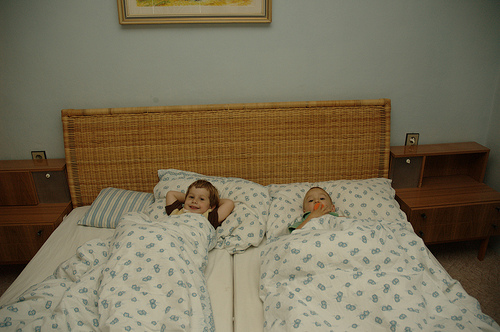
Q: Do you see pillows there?
A: Yes, there is a pillow.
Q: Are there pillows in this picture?
A: Yes, there is a pillow.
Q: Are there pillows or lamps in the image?
A: Yes, there is a pillow.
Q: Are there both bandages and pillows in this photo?
A: No, there is a pillow but no bandages.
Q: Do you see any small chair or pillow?
A: Yes, there is a small pillow.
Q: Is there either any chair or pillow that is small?
A: Yes, the pillow is small.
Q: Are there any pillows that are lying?
A: Yes, there is a pillow that is lying.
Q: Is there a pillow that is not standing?
A: Yes, there is a pillow that is lying.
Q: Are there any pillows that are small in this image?
A: Yes, there is a small pillow.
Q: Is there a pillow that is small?
A: Yes, there is a pillow that is small.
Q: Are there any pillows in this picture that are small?
A: Yes, there is a pillow that is small.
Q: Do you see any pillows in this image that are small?
A: Yes, there is a pillow that is small.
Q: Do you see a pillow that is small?
A: Yes, there is a pillow that is small.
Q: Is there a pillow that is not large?
A: Yes, there is a small pillow.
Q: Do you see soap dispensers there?
A: No, there are no soap dispensers.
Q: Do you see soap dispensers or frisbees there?
A: No, there are no soap dispensers or frisbees.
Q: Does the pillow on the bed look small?
A: Yes, the pillow is small.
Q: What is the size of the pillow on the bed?
A: The pillow is small.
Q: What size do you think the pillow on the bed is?
A: The pillow is small.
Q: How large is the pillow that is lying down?
A: The pillow is small.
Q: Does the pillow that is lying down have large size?
A: No, the pillow is small.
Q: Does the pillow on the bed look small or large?
A: The pillow is small.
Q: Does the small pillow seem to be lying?
A: Yes, the pillow is lying.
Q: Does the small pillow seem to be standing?
A: No, the pillow is lying.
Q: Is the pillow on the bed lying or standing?
A: The pillow is lying.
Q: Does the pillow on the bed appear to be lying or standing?
A: The pillow is lying.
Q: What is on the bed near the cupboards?
A: The pillow is on the bed.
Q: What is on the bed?
A: The pillow is on the bed.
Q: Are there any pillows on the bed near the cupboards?
A: Yes, there is a pillow on the bed.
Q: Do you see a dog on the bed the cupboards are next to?
A: No, there is a pillow on the bed.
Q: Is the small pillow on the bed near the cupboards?
A: Yes, the pillow is on the bed.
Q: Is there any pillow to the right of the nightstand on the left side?
A: Yes, there is a pillow to the right of the nightstand.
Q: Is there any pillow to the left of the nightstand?
A: No, the pillow is to the right of the nightstand.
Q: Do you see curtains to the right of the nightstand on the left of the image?
A: No, there is a pillow to the right of the nightstand.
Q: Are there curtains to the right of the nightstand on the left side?
A: No, there is a pillow to the right of the nightstand.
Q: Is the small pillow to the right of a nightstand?
A: Yes, the pillow is to the right of a nightstand.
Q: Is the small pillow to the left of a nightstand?
A: No, the pillow is to the right of a nightstand.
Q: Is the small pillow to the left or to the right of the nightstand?
A: The pillow is to the right of the nightstand.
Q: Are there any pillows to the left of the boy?
A: Yes, there is a pillow to the left of the boy.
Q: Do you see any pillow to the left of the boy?
A: Yes, there is a pillow to the left of the boy.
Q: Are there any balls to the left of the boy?
A: No, there is a pillow to the left of the boy.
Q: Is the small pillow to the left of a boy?
A: Yes, the pillow is to the left of a boy.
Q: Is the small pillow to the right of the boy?
A: No, the pillow is to the left of the boy.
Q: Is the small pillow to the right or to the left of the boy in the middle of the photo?
A: The pillow is to the left of the boy.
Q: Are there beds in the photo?
A: Yes, there is a bed.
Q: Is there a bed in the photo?
A: Yes, there is a bed.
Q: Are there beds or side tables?
A: Yes, there is a bed.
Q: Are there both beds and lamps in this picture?
A: No, there is a bed but no lamps.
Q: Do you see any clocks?
A: No, there are no clocks.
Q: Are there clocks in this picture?
A: No, there are no clocks.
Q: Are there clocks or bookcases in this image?
A: No, there are no clocks or bookcases.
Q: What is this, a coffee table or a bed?
A: This is a bed.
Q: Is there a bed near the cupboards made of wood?
A: Yes, there is a bed near the cupboards.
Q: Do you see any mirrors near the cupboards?
A: No, there is a bed near the cupboards.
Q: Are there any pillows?
A: Yes, there is a pillow.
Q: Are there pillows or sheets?
A: Yes, there is a pillow.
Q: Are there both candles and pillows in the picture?
A: No, there is a pillow but no candles.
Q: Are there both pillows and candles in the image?
A: No, there is a pillow but no candles.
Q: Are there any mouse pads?
A: No, there are no mouse pads.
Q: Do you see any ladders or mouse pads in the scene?
A: No, there are no mouse pads or ladders.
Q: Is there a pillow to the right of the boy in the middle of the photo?
A: Yes, there is a pillow to the right of the boy.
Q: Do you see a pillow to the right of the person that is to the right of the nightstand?
A: Yes, there is a pillow to the right of the boy.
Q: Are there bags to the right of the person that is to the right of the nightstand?
A: No, there is a pillow to the right of the boy.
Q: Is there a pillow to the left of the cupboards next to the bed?
A: Yes, there is a pillow to the left of the cupboards.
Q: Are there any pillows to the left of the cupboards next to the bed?
A: Yes, there is a pillow to the left of the cupboards.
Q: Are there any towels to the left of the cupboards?
A: No, there is a pillow to the left of the cupboards.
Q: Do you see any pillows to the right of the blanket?
A: Yes, there is a pillow to the right of the blanket.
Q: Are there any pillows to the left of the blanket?
A: No, the pillow is to the right of the blanket.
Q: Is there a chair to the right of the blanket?
A: No, there is a pillow to the right of the blanket.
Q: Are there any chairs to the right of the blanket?
A: No, there is a pillow to the right of the blanket.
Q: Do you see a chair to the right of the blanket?
A: No, there is a pillow to the right of the blanket.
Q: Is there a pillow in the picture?
A: Yes, there is a pillow.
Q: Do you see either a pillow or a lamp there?
A: Yes, there is a pillow.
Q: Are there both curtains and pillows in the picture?
A: No, there is a pillow but no curtains.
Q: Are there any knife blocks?
A: No, there are no knife blocks.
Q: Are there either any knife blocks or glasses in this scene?
A: No, there are no knife blocks or glasses.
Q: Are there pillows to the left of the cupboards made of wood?
A: Yes, there is a pillow to the left of the cupboards.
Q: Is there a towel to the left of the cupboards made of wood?
A: No, there is a pillow to the left of the cupboards.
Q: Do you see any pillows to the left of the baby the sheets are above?
A: Yes, there is a pillow to the left of the baby.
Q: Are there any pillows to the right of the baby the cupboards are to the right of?
A: No, the pillow is to the left of the baby.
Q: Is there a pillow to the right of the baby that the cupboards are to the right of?
A: No, the pillow is to the left of the baby.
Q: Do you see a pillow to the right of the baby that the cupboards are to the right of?
A: No, the pillow is to the left of the baby.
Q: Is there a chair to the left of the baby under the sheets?
A: No, there is a pillow to the left of the baby.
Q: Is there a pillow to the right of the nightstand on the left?
A: Yes, there is a pillow to the right of the nightstand.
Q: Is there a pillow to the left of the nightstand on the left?
A: No, the pillow is to the right of the nightstand.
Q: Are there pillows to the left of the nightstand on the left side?
A: No, the pillow is to the right of the nightstand.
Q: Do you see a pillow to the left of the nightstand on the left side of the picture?
A: No, the pillow is to the right of the nightstand.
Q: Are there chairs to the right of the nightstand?
A: No, there is a pillow to the right of the nightstand.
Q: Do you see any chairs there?
A: No, there are no chairs.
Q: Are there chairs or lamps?
A: No, there are no chairs or lamps.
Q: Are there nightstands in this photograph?
A: Yes, there is a nightstand.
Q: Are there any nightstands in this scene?
A: Yes, there is a nightstand.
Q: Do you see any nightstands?
A: Yes, there is a nightstand.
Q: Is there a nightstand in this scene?
A: Yes, there is a nightstand.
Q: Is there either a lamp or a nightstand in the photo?
A: Yes, there is a nightstand.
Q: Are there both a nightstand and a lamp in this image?
A: No, there is a nightstand but no lamps.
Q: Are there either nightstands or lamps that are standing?
A: Yes, the nightstand is standing.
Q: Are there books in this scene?
A: No, there are no books.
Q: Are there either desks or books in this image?
A: No, there are no books or desks.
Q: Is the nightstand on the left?
A: Yes, the nightstand is on the left of the image.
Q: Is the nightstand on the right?
A: No, the nightstand is on the left of the image.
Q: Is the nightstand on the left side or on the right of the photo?
A: The nightstand is on the left of the image.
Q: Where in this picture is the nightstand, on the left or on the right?
A: The nightstand is on the left of the image.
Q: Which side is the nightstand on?
A: The nightstand is on the left of the image.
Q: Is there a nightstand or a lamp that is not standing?
A: No, there is a nightstand but it is standing.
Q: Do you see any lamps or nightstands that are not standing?
A: No, there is a nightstand but it is standing.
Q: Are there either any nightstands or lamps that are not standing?
A: No, there is a nightstand but it is standing.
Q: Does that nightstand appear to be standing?
A: Yes, the nightstand is standing.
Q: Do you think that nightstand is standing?
A: Yes, the nightstand is standing.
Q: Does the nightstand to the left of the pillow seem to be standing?
A: Yes, the nightstand is standing.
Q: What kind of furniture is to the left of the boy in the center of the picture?
A: The piece of furniture is a nightstand.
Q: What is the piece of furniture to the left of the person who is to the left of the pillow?
A: The piece of furniture is a nightstand.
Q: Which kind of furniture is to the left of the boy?
A: The piece of furniture is a nightstand.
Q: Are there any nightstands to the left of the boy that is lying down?
A: Yes, there is a nightstand to the left of the boy.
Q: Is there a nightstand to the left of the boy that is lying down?
A: Yes, there is a nightstand to the left of the boy.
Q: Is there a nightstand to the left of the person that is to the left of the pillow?
A: Yes, there is a nightstand to the left of the boy.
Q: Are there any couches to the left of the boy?
A: No, there is a nightstand to the left of the boy.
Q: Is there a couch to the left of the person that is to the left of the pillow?
A: No, there is a nightstand to the left of the boy.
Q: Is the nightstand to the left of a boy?
A: Yes, the nightstand is to the left of a boy.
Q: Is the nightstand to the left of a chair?
A: No, the nightstand is to the left of a boy.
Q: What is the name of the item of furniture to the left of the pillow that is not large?
A: The piece of furniture is a nightstand.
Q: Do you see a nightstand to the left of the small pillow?
A: Yes, there is a nightstand to the left of the pillow.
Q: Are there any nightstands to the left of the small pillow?
A: Yes, there is a nightstand to the left of the pillow.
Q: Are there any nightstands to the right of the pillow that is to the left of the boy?
A: No, the nightstand is to the left of the pillow.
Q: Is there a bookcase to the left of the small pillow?
A: No, there is a nightstand to the left of the pillow.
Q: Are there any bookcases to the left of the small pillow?
A: No, there is a nightstand to the left of the pillow.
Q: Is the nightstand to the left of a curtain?
A: No, the nightstand is to the left of a pillow.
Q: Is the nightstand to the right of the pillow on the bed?
A: No, the nightstand is to the left of the pillow.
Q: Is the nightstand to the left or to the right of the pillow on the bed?
A: The nightstand is to the left of the pillow.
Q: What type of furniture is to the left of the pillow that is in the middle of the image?
A: The piece of furniture is a nightstand.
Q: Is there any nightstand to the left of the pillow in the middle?
A: Yes, there is a nightstand to the left of the pillow.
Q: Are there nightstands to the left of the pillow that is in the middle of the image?
A: Yes, there is a nightstand to the left of the pillow.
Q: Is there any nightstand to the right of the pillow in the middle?
A: No, the nightstand is to the left of the pillow.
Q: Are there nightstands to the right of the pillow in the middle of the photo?
A: No, the nightstand is to the left of the pillow.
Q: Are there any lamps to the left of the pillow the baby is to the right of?
A: No, there is a nightstand to the left of the pillow.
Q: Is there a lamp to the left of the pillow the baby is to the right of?
A: No, there is a nightstand to the left of the pillow.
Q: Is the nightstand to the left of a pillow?
A: Yes, the nightstand is to the left of a pillow.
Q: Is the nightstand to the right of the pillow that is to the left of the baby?
A: No, the nightstand is to the left of the pillow.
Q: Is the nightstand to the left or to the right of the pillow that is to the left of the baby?
A: The nightstand is to the left of the pillow.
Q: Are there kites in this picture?
A: No, there are no kites.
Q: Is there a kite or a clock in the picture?
A: No, there are no kites or clocks.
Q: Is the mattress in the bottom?
A: Yes, the mattress is in the bottom of the image.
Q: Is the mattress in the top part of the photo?
A: No, the mattress is in the bottom of the image.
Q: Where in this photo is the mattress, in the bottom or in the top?
A: The mattress is in the bottom of the image.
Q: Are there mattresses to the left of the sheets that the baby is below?
A: Yes, there is a mattress to the left of the sheets.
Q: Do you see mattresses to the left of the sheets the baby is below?
A: Yes, there is a mattress to the left of the sheets.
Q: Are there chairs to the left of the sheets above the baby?
A: No, there is a mattress to the left of the sheets.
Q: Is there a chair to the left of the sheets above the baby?
A: No, there is a mattress to the left of the sheets.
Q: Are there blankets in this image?
A: Yes, there is a blanket.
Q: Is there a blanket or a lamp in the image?
A: Yes, there is a blanket.